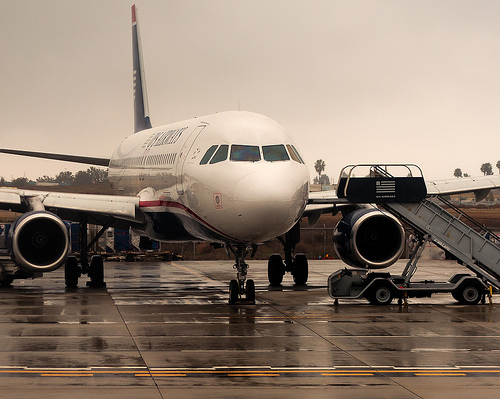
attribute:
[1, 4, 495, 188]
sky — grey, cloudy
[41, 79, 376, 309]
plane — accent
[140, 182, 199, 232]
stripe — red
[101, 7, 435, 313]
airplane — white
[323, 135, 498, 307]
stairs — loading, portible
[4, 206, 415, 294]
engines — white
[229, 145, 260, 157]
window — multipule, windshield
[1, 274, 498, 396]
ground — wet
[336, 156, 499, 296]
steps — grey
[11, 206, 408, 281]
engines — black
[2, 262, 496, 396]
pavement — wet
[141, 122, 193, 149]
logo — airline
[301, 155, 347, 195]
tree — tall, palm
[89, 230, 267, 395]
platform — wheeled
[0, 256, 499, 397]
tarmac — grey, wet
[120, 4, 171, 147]
tail — red, white, blue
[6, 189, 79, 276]
engine — black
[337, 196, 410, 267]
engine — black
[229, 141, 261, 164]
window — rectangular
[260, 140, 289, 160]
window — rectangular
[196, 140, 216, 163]
window — rectangular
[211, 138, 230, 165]
window — rectangular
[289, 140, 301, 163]
window — rectangular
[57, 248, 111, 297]
wheel — back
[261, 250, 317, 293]
wheel — back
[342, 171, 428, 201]
partition — black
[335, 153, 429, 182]
railings — curved, grey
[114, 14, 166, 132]
tail — blue